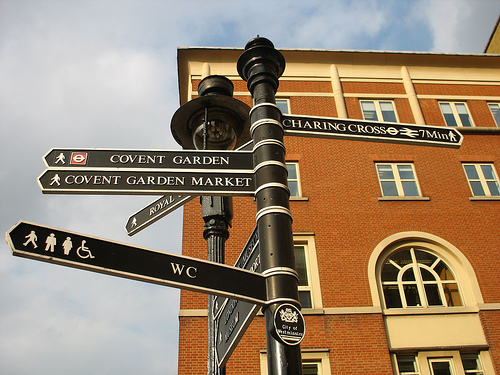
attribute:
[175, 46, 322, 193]
sign — circle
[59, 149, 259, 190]
signs — large and black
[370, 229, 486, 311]
window — arched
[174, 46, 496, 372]
building —  brick, large and brick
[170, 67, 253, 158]
streetlight — tall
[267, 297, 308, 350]
sign — circle 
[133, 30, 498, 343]
building — large, red and brick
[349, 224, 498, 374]
window — arched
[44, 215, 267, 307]
sign —  black